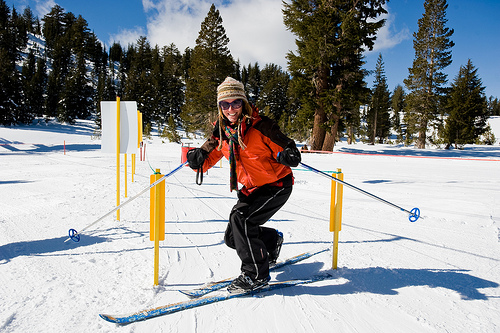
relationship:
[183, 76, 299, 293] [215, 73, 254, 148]
woman wearing hat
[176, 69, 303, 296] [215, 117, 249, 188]
girl has scarf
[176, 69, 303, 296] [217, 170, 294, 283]
girl has pants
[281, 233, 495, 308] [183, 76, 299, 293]
shadow from woman